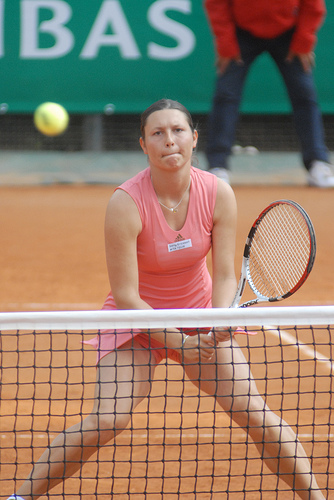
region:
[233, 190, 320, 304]
the tennis player's racket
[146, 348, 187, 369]
the tennis player's bloomers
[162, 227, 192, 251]
a peice of clothing manufactured by Adidas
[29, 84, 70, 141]
the tennis ball in flight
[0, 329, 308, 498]
the net of the tennis court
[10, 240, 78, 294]
a dirt tennis court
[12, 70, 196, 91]
a green banner in the background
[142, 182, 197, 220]
the tennis player's necklace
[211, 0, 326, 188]
a man wearing a red sweater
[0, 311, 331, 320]
the top of the net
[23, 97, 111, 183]
ball is in air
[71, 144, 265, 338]
woman's outfit is pink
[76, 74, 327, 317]
woman is holding tennis racket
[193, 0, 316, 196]
man has hands on knees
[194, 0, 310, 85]
man's shirt is red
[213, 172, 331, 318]
racket is red black and white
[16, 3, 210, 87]
letters say BAS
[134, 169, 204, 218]
woman is wearing necklace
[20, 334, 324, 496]
woman's legs are spread apart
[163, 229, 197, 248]
addidas symbol on front of shirt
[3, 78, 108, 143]
the ball is in the air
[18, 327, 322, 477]
the net is black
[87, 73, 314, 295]
the woman is holding a tennis racket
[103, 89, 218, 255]
the woman`s shirt is pink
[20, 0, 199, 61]
the letters are bas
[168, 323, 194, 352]
the woman is wearing a bracelet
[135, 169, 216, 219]
a silver metal necklace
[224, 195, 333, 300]
the tennis racket is black and red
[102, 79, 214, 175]
the woman has brown hair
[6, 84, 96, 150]
the ball is yellowish green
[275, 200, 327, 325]
picture of a tennis racket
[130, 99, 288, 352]
a woman wearing pink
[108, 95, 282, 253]
a woman playing tennis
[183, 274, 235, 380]
gripping a tennis racket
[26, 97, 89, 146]
a flying tennis ball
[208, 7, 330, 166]
a person wearing a red shirt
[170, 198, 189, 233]
a necklace in picture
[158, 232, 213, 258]
a white colored nametag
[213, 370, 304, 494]
a tennis player's leg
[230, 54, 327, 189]
a person wearing blue jeans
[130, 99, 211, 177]
woman's lips are pursed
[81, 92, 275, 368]
woman wears peach-colored tennis dress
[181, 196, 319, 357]
woman grips tennis racket with both hands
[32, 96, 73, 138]
yellow tennis ball in the air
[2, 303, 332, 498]
net in foreground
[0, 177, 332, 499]
clay tennis court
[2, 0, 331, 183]
chain-link fence behind tennis court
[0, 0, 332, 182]
green tarp hangs over the fence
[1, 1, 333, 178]
green tarp has white letters saying BAS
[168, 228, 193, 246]
adidas logo on front of tennis dress